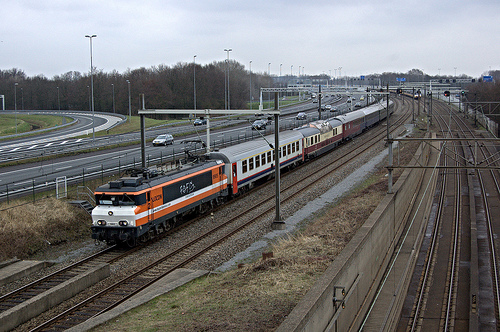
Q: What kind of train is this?
A: Passenger.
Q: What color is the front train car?
A: Orange and white.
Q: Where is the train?
A: On the rails.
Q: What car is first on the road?
A: Silver van.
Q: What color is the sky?
A: Grey.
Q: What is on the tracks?
A: Train.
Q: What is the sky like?
A: Overcast.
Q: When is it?
A: Afternoon.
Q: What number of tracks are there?
A: 4.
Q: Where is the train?
A: On the tracks.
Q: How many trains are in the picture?
A: 1.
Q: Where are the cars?
A: On the road.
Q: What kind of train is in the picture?
A: Passenger train.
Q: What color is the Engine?
A: Orange and white.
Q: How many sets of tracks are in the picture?
A: 4.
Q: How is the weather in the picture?
A: Cloudy.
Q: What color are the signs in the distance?
A: Blue.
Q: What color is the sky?
A: Gray.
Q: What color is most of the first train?
A: Orange.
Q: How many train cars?
A: Six.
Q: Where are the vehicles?
A: The road.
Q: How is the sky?
A: Cloudy.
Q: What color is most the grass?
A: Brown.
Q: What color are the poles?
A: Silver.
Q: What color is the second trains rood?
A: Gray.